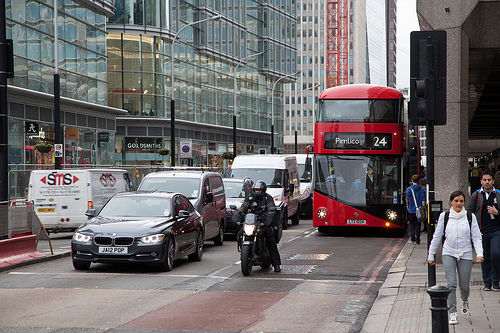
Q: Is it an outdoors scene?
A: Yes, it is outdoors.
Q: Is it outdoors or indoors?
A: It is outdoors.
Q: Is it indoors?
A: No, it is outdoors.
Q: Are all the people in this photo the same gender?
A: No, they are both male and female.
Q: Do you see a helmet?
A: Yes, there is a helmet.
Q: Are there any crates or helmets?
A: Yes, there is a helmet.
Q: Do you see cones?
A: No, there are no cones.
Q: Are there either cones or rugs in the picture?
A: No, there are no cones or rugs.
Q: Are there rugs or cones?
A: No, there are no cones or rugs.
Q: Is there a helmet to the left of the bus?
A: Yes, there is a helmet to the left of the bus.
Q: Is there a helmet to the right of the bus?
A: No, the helmet is to the left of the bus.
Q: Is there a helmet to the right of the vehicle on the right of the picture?
A: No, the helmet is to the left of the bus.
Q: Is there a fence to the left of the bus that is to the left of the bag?
A: No, there is a helmet to the left of the bus.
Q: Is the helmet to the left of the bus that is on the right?
A: Yes, the helmet is to the left of the bus.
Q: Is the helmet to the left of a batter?
A: No, the helmet is to the left of the bus.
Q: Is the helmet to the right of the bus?
A: No, the helmet is to the left of the bus.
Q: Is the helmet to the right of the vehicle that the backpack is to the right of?
A: No, the helmet is to the left of the bus.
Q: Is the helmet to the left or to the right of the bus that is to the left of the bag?
A: The helmet is to the left of the bus.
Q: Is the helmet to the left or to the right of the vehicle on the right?
A: The helmet is to the left of the bus.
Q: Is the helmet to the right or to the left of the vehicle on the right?
A: The helmet is to the left of the bus.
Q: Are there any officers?
A: No, there are no officers.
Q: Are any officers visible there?
A: No, there are no officers.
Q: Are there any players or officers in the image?
A: No, there are no officers or players.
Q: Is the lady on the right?
A: Yes, the lady is on the right of the image.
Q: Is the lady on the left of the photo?
A: No, the lady is on the right of the image.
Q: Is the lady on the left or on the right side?
A: The lady is on the right of the image.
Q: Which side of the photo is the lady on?
A: The lady is on the right of the image.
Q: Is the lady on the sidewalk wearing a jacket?
A: Yes, the lady is wearing a jacket.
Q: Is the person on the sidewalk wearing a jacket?
A: Yes, the lady is wearing a jacket.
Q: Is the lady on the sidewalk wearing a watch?
A: No, the lady is wearing a jacket.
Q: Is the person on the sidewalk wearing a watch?
A: No, the lady is wearing a jacket.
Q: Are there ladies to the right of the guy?
A: Yes, there is a lady to the right of the guy.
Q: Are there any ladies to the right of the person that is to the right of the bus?
A: Yes, there is a lady to the right of the guy.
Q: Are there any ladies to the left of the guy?
A: No, the lady is to the right of the guy.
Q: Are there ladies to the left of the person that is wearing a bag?
A: No, the lady is to the right of the guy.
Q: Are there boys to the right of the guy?
A: No, there is a lady to the right of the guy.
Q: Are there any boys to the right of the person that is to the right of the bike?
A: No, there is a lady to the right of the guy.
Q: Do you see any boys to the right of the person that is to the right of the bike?
A: No, there is a lady to the right of the guy.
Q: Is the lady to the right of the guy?
A: Yes, the lady is to the right of the guy.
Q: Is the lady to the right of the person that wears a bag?
A: Yes, the lady is to the right of the guy.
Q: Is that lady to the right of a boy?
A: No, the lady is to the right of the guy.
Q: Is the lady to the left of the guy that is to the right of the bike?
A: No, the lady is to the right of the guy.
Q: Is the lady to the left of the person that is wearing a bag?
A: No, the lady is to the right of the guy.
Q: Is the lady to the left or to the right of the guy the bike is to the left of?
A: The lady is to the right of the guy.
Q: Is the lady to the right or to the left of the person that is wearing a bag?
A: The lady is to the right of the guy.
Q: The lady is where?
A: The lady is on the sidewalk.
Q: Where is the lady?
A: The lady is on the sidewalk.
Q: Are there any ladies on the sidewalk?
A: Yes, there is a lady on the sidewalk.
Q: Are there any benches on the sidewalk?
A: No, there is a lady on the sidewalk.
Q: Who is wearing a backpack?
A: The lady is wearing a backpack.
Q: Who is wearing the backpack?
A: The lady is wearing a backpack.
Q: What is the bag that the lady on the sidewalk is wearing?
A: The bag is a backpack.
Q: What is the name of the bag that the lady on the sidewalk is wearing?
A: The bag is a backpack.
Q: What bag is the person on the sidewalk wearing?
A: The lady is wearing a backpack.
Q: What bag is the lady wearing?
A: The lady is wearing a backpack.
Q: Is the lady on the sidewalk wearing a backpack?
A: Yes, the lady is wearing a backpack.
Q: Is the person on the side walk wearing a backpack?
A: Yes, the lady is wearing a backpack.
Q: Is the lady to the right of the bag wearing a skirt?
A: No, the lady is wearing a backpack.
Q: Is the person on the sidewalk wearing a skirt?
A: No, the lady is wearing a backpack.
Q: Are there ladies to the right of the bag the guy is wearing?
A: Yes, there is a lady to the right of the bag.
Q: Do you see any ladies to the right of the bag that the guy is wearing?
A: Yes, there is a lady to the right of the bag.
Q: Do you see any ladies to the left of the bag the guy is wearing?
A: No, the lady is to the right of the bag.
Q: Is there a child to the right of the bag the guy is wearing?
A: No, there is a lady to the right of the bag.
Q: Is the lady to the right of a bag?
A: Yes, the lady is to the right of a bag.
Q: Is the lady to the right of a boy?
A: No, the lady is to the right of a bag.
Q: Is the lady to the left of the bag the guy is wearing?
A: No, the lady is to the right of the bag.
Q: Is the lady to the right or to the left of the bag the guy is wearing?
A: The lady is to the right of the bag.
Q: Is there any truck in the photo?
A: No, there are no trucks.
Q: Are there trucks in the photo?
A: No, there are no trucks.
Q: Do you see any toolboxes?
A: No, there are no toolboxes.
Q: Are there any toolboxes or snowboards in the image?
A: No, there are no toolboxes or snowboards.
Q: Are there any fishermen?
A: No, there are no fishermen.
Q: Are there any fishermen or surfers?
A: No, there are no fishermen or surfers.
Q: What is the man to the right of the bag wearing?
A: The man is wearing a jacket.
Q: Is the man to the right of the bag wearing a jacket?
A: Yes, the man is wearing a jacket.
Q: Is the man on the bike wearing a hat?
A: No, the man is wearing a jacket.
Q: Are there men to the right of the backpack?
A: Yes, there is a man to the right of the backpack.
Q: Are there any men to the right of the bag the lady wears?
A: Yes, there is a man to the right of the backpack.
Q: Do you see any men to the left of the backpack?
A: No, the man is to the right of the backpack.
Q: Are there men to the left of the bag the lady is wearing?
A: No, the man is to the right of the backpack.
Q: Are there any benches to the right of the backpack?
A: No, there is a man to the right of the backpack.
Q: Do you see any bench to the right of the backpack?
A: No, there is a man to the right of the backpack.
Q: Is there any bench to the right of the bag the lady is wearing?
A: No, there is a man to the right of the backpack.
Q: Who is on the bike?
A: The man is on the bike.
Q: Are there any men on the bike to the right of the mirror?
A: Yes, there is a man on the bike.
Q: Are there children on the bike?
A: No, there is a man on the bike.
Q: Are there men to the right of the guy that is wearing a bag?
A: Yes, there is a man to the right of the guy.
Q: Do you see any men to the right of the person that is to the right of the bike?
A: Yes, there is a man to the right of the guy.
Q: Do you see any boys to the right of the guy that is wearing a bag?
A: No, there is a man to the right of the guy.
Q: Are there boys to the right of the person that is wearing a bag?
A: No, there is a man to the right of the guy.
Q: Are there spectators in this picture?
A: No, there are no spectators.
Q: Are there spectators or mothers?
A: No, there are no spectators or mothers.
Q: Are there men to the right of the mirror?
A: Yes, there is a man to the right of the mirror.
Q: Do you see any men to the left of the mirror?
A: No, the man is to the right of the mirror.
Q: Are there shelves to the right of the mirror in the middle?
A: No, there is a man to the right of the mirror.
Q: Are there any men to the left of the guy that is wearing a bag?
A: Yes, there is a man to the left of the guy.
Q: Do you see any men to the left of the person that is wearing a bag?
A: Yes, there is a man to the left of the guy.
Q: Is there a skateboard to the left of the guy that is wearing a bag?
A: No, there is a man to the left of the guy.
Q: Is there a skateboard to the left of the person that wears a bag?
A: No, there is a man to the left of the guy.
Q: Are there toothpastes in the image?
A: No, there are no toothpastes.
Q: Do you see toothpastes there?
A: No, there are no toothpastes.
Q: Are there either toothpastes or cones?
A: No, there are no toothpastes or cones.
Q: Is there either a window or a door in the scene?
A: Yes, there are windows.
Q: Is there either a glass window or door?
A: Yes, there are glass windows.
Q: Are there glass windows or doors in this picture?
A: Yes, there are glass windows.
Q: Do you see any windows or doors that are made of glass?
A: Yes, the windows are made of glass.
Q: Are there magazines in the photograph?
A: No, there are no magazines.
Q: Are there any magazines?
A: No, there are no magazines.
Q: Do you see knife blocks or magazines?
A: No, there are no magazines or knife blocks.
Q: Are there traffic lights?
A: Yes, there is a traffic light.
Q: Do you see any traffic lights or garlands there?
A: Yes, there is a traffic light.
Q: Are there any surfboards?
A: No, there are no surfboards.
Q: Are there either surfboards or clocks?
A: No, there are no surfboards or clocks.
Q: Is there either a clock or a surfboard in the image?
A: No, there are no surfboards or clocks.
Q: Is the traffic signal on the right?
A: Yes, the traffic signal is on the right of the image.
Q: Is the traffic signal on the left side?
A: No, the traffic signal is on the right of the image.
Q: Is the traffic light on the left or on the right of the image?
A: The traffic light is on the right of the image.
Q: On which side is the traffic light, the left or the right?
A: The traffic light is on the right of the image.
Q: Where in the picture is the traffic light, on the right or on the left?
A: The traffic light is on the right of the image.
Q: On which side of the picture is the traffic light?
A: The traffic light is on the right of the image.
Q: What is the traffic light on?
A: The traffic light is on the pole.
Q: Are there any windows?
A: Yes, there is a window.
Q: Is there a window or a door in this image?
A: Yes, there is a window.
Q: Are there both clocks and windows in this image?
A: No, there is a window but no clocks.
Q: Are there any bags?
A: Yes, there is a bag.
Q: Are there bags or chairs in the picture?
A: Yes, there is a bag.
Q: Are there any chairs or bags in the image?
A: Yes, there is a bag.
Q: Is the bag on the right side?
A: Yes, the bag is on the right of the image.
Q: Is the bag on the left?
A: No, the bag is on the right of the image.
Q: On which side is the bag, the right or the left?
A: The bag is on the right of the image.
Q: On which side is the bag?
A: The bag is on the right of the image.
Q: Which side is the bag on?
A: The bag is on the right of the image.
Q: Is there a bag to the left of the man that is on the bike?
A: Yes, there is a bag to the left of the man.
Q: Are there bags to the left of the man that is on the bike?
A: Yes, there is a bag to the left of the man.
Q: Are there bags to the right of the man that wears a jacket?
A: No, the bag is to the left of the man.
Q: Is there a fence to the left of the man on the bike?
A: No, there is a bag to the left of the man.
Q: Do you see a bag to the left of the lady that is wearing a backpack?
A: Yes, there is a bag to the left of the lady.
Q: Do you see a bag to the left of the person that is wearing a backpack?
A: Yes, there is a bag to the left of the lady.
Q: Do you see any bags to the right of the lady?
A: No, the bag is to the left of the lady.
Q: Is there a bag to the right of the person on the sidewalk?
A: No, the bag is to the left of the lady.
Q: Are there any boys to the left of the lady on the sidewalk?
A: No, there is a bag to the left of the lady.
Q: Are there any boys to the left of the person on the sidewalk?
A: No, there is a bag to the left of the lady.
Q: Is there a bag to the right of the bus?
A: Yes, there is a bag to the right of the bus.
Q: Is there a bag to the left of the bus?
A: No, the bag is to the right of the bus.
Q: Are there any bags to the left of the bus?
A: No, the bag is to the right of the bus.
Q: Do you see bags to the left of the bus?
A: No, the bag is to the right of the bus.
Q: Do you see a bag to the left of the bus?
A: No, the bag is to the right of the bus.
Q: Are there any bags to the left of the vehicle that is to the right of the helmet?
A: No, the bag is to the right of the bus.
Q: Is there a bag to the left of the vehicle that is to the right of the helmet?
A: No, the bag is to the right of the bus.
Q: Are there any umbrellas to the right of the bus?
A: No, there is a bag to the right of the bus.